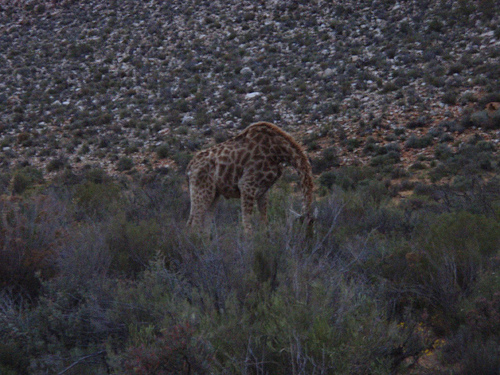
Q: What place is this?
A: It is a field.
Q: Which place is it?
A: It is a field.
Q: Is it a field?
A: Yes, it is a field.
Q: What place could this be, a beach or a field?
A: It is a field.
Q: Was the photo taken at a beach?
A: No, the picture was taken in a field.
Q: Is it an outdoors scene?
A: Yes, it is outdoors.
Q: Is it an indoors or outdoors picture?
A: It is outdoors.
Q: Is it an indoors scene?
A: No, it is outdoors.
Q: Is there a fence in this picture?
A: No, there are no fences.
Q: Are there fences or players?
A: No, there are no fences or players.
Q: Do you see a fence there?
A: No, there are no fences.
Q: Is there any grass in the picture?
A: Yes, there is grass.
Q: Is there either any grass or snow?
A: Yes, there is grass.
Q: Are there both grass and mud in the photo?
A: No, there is grass but no mud.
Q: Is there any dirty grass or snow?
A: Yes, there is dirty grass.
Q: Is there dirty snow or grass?
A: Yes, there is dirty grass.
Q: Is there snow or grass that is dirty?
A: Yes, the grass is dirty.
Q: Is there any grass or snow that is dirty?
A: Yes, the grass is dirty.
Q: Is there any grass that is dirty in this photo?
A: Yes, there is dirty grass.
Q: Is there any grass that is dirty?
A: Yes, there is grass that is dirty.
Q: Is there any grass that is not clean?
A: Yes, there is dirty grass.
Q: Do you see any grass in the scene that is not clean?
A: Yes, there is dirty grass.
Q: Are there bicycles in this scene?
A: No, there are no bicycles.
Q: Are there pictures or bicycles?
A: No, there are no bicycles or pictures.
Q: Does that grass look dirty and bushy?
A: Yes, the grass is dirty and bushy.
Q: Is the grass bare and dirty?
A: No, the grass is dirty but bushy.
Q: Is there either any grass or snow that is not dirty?
A: No, there is grass but it is dirty.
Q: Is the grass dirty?
A: Yes, the grass is dirty.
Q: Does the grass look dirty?
A: Yes, the grass is dirty.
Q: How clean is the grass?
A: The grass is dirty.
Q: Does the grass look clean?
A: No, the grass is dirty.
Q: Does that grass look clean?
A: No, the grass is dirty.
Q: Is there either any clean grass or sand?
A: No, there is grass but it is dirty.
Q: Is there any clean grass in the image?
A: No, there is grass but it is dirty.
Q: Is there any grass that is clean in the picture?
A: No, there is grass but it is dirty.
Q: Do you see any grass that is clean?
A: No, there is grass but it is dirty.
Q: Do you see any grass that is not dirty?
A: No, there is grass but it is dirty.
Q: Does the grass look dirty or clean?
A: The grass is dirty.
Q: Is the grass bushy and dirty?
A: Yes, the grass is bushy and dirty.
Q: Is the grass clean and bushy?
A: No, the grass is bushy but dirty.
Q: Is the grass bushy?
A: Yes, the grass is bushy.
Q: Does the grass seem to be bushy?
A: Yes, the grass is bushy.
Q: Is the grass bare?
A: No, the grass is bushy.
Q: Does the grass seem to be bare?
A: No, the grass is bushy.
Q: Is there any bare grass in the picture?
A: No, there is grass but it is bushy.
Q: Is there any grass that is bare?
A: No, there is grass but it is bushy.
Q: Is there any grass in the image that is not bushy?
A: No, there is grass but it is bushy.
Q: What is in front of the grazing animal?
A: The grass is in front of the giraffe.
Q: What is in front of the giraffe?
A: The grass is in front of the giraffe.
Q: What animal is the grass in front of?
A: The grass is in front of the giraffe.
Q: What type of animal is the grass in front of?
A: The grass is in front of the giraffe.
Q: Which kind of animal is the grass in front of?
A: The grass is in front of the giraffe.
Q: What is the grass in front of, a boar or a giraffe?
A: The grass is in front of a giraffe.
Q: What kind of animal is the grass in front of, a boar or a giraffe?
A: The grass is in front of a giraffe.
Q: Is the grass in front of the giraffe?
A: Yes, the grass is in front of the giraffe.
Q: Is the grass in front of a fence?
A: No, the grass is in front of the giraffe.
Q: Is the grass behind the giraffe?
A: No, the grass is in front of the giraffe.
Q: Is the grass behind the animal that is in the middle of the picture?
A: No, the grass is in front of the giraffe.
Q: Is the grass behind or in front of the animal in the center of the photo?
A: The grass is in front of the giraffe.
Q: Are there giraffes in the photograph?
A: Yes, there is a giraffe.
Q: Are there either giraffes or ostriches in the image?
A: Yes, there is a giraffe.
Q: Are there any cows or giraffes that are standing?
A: Yes, the giraffe is standing.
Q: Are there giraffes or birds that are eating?
A: Yes, the giraffe is eating.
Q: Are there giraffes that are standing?
A: Yes, there is a giraffe that is standing.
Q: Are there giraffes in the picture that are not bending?
A: Yes, there is a giraffe that is standing.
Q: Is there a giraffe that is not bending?
A: Yes, there is a giraffe that is standing.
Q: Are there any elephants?
A: No, there are no elephants.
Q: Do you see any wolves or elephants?
A: No, there are no elephants or wolves.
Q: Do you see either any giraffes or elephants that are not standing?
A: No, there is a giraffe but it is standing.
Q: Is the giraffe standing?
A: Yes, the giraffe is standing.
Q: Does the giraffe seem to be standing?
A: Yes, the giraffe is standing.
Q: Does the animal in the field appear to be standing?
A: Yes, the giraffe is standing.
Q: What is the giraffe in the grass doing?
A: The giraffe is standing.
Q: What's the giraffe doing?
A: The giraffe is standing.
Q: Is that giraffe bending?
A: No, the giraffe is standing.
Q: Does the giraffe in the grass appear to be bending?
A: No, the giraffe is standing.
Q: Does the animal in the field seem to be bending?
A: No, the giraffe is standing.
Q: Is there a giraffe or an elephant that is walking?
A: No, there is a giraffe but it is standing.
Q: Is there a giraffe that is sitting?
A: No, there is a giraffe but it is standing.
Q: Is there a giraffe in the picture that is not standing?
A: No, there is a giraffe but it is standing.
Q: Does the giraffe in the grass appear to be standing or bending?
A: The giraffe is standing.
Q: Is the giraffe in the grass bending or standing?
A: The giraffe is standing.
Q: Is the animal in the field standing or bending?
A: The giraffe is standing.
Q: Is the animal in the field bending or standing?
A: The giraffe is standing.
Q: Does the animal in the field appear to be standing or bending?
A: The giraffe is standing.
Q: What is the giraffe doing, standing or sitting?
A: The giraffe is standing.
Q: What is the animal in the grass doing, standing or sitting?
A: The giraffe is standing.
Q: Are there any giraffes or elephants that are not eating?
A: No, there is a giraffe but it is eating.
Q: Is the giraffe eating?
A: Yes, the giraffe is eating.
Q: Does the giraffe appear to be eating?
A: Yes, the giraffe is eating.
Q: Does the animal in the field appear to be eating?
A: Yes, the giraffe is eating.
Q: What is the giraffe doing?
A: The giraffe is eating.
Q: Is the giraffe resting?
A: No, the giraffe is eating.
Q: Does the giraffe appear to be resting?
A: No, the giraffe is eating.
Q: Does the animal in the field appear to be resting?
A: No, the giraffe is eating.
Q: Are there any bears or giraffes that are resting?
A: No, there is a giraffe but it is eating.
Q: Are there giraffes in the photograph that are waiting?
A: No, there is a giraffe but it is eating.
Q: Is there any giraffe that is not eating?
A: No, there is a giraffe but it is eating.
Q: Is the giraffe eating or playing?
A: The giraffe is eating.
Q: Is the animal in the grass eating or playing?
A: The giraffe is eating.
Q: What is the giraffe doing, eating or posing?
A: The giraffe is eating.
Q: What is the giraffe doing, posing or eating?
A: The giraffe is eating.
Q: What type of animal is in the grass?
A: The animal is a giraffe.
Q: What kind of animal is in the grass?
A: The animal is a giraffe.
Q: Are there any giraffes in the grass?
A: Yes, there is a giraffe in the grass.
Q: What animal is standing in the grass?
A: The giraffe is standing in the grass.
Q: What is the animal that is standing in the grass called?
A: The animal is a giraffe.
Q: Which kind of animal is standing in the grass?
A: The animal is a giraffe.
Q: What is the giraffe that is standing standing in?
A: The giraffe is standing in the grass.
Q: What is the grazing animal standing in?
A: The giraffe is standing in the grass.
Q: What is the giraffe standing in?
A: The giraffe is standing in the grass.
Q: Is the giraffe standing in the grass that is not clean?
A: Yes, the giraffe is standing in the grass.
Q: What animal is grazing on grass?
A: The giraffe is grazing on grass.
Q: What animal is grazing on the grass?
A: The giraffe is grazing on grass.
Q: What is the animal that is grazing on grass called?
A: The animal is a giraffe.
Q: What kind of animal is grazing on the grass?
A: The animal is a giraffe.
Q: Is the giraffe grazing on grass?
A: Yes, the giraffe is grazing on grass.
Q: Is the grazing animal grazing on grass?
A: Yes, the giraffe is grazing on grass.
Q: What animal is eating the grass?
A: The giraffe is eating the grass.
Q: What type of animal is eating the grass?
A: The animal is a giraffe.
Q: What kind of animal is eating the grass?
A: The animal is a giraffe.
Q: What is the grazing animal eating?
A: The giraffe is eating grass.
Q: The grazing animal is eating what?
A: The giraffe is eating grass.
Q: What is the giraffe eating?
A: The giraffe is eating grass.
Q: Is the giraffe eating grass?
A: Yes, the giraffe is eating grass.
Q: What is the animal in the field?
A: The animal is a giraffe.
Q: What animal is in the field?
A: The animal is a giraffe.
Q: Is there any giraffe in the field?
A: Yes, there is a giraffe in the field.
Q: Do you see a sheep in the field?
A: No, there is a giraffe in the field.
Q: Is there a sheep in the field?
A: No, there is a giraffe in the field.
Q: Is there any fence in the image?
A: No, there are no fences.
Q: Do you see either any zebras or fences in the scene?
A: No, there are no fences or zebras.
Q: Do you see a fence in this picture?
A: No, there are no fences.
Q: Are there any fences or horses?
A: No, there are no fences or horses.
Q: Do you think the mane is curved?
A: Yes, the mane is curved.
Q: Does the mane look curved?
A: Yes, the mane is curved.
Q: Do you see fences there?
A: No, there are no fences.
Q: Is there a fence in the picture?
A: No, there are no fences.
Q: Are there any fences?
A: No, there are no fences.